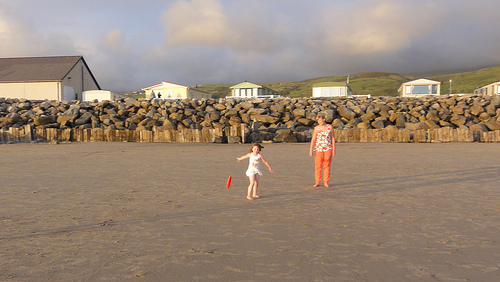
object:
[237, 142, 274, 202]
girl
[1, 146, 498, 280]
sand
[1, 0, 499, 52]
sky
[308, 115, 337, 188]
woman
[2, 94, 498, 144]
seawall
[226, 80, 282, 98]
buildings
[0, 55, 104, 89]
roof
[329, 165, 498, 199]
shadows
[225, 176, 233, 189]
frisbee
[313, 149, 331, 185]
pants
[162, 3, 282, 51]
cloud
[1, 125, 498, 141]
fence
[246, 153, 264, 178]
dress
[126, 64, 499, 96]
hill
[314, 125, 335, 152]
tank